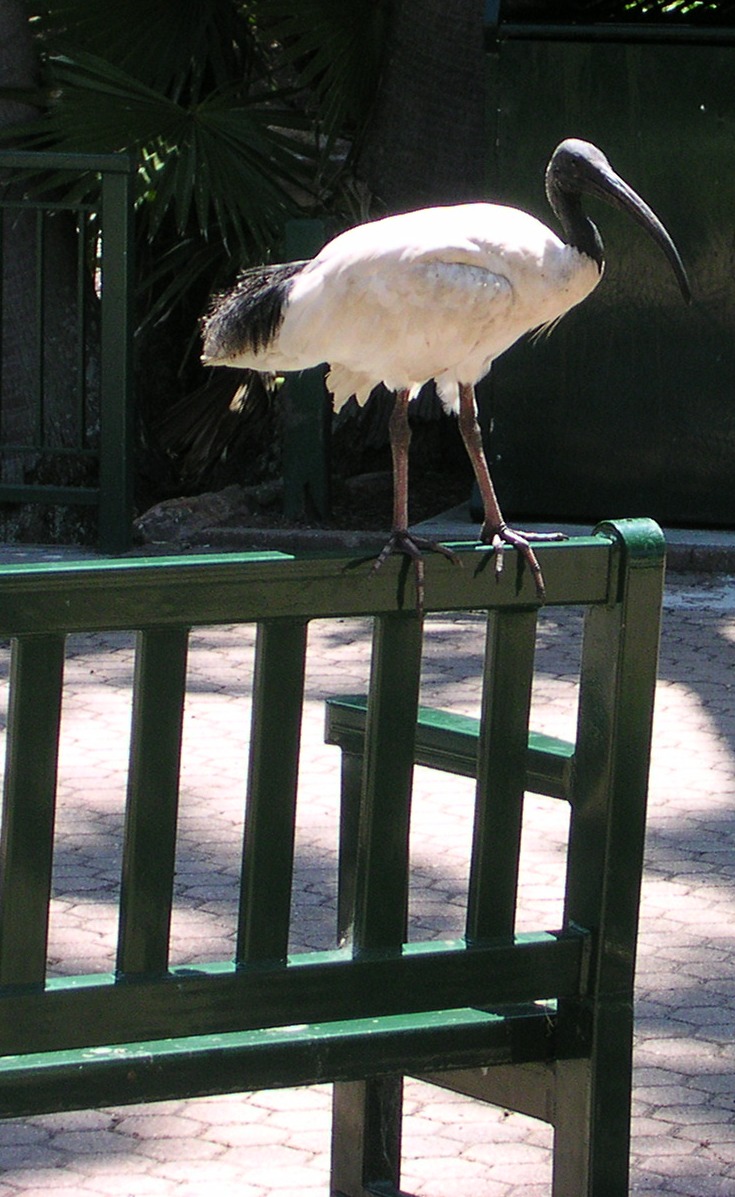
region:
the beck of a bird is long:
[601, 169, 706, 305]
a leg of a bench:
[318, 1064, 644, 1196]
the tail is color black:
[180, 253, 309, 382]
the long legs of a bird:
[336, 389, 575, 615]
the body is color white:
[265, 190, 607, 412]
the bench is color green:
[6, 503, 679, 1192]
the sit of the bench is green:
[0, 932, 554, 1124]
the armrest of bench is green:
[314, 680, 574, 800]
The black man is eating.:
[703, 1068, 728, 1096]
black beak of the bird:
[607, 172, 701, 302]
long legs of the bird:
[363, 388, 550, 605]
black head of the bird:
[548, 137, 609, 196]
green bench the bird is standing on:
[5, 533, 640, 1196]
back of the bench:
[3, 548, 592, 1006]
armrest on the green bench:
[322, 680, 570, 807]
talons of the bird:
[355, 517, 555, 610]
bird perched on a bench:
[172, 94, 686, 612]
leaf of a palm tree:
[42, 32, 346, 253]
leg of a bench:
[325, 1065, 408, 1195]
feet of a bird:
[349, 517, 579, 614]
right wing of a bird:
[345, 244, 518, 389]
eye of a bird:
[557, 152, 584, 182]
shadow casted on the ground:
[667, 591, 729, 730]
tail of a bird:
[188, 268, 287, 390]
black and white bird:
[177, 127, 693, 608]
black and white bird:
[183, 121, 690, 605]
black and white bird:
[174, 95, 689, 626]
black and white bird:
[143, 88, 697, 608]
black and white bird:
[179, 87, 714, 621]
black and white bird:
[140, 114, 707, 616]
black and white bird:
[161, 123, 698, 617]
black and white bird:
[183, 125, 715, 596]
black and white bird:
[183, 129, 733, 609]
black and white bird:
[178, 126, 708, 610]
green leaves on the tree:
[224, 97, 276, 160]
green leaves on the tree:
[243, 163, 276, 222]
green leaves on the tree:
[203, 86, 248, 225]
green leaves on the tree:
[156, 389, 250, 466]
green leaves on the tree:
[272, 60, 350, 147]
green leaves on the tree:
[95, 50, 278, 215]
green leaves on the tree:
[43, 23, 148, 173]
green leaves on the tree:
[154, 32, 253, 189]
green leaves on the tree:
[207, 32, 329, 252]